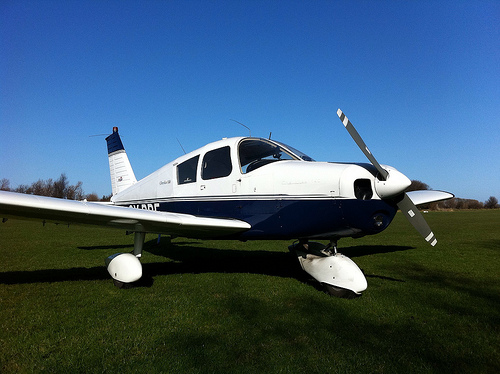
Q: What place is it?
A: It is a field.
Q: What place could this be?
A: It is a field.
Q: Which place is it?
A: It is a field.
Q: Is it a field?
A: Yes, it is a field.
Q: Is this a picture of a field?
A: Yes, it is showing a field.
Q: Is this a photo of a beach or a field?
A: It is showing a field.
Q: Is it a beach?
A: No, it is a field.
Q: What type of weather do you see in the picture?
A: It is clear.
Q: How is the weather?
A: It is clear.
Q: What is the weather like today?
A: It is clear.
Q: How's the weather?
A: It is clear.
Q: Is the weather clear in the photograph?
A: Yes, it is clear.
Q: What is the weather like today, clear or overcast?
A: It is clear.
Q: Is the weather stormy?
A: No, it is clear.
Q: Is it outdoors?
A: Yes, it is outdoors.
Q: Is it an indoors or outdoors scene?
A: It is outdoors.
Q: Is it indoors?
A: No, it is outdoors.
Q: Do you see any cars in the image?
A: No, there are no cars.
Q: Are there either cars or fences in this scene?
A: No, there are no cars or fences.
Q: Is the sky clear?
A: Yes, the sky is clear.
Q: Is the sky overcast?
A: No, the sky is clear.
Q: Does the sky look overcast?
A: No, the sky is clear.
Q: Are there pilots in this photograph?
A: No, there are no pilots.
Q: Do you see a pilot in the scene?
A: No, there are no pilots.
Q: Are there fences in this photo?
A: No, there are no fences.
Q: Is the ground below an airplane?
A: Yes, the ground is below an airplane.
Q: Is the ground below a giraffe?
A: No, the ground is below an airplane.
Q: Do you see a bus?
A: No, there are no buses.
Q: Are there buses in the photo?
A: No, there are no buses.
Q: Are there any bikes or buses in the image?
A: No, there are no buses or bikes.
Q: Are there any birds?
A: No, there are no birds.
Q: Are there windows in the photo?
A: Yes, there is a window.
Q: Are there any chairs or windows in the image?
A: Yes, there is a window.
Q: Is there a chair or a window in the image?
A: Yes, there is a window.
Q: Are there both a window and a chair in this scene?
A: No, there is a window but no chairs.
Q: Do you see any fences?
A: No, there are no fences.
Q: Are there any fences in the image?
A: No, there are no fences.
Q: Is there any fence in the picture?
A: No, there are no fences.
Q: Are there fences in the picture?
A: No, there are no fences.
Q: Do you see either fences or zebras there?
A: No, there are no fences or zebras.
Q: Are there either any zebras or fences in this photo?
A: No, there are no fences or zebras.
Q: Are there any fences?
A: No, there are no fences.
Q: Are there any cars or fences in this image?
A: No, there are no fences or cars.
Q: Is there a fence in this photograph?
A: No, there are no fences.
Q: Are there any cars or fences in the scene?
A: No, there are no fences or cars.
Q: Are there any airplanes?
A: Yes, there is an airplane.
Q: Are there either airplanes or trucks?
A: Yes, there is an airplane.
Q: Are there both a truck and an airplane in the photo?
A: No, there is an airplane but no trucks.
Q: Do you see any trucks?
A: No, there are no trucks.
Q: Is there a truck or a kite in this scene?
A: No, there are no trucks or kites.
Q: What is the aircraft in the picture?
A: The aircraft is an airplane.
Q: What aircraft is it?
A: The aircraft is an airplane.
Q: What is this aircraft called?
A: This is an airplane.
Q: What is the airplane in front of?
A: The airplane is in front of the trees.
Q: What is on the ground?
A: The airplane is on the ground.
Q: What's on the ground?
A: The airplane is on the ground.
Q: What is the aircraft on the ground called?
A: The aircraft is an airplane.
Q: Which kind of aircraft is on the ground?
A: The aircraft is an airplane.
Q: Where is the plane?
A: The plane is on the ground.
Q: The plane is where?
A: The plane is on the ground.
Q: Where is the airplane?
A: The plane is on the ground.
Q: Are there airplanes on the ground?
A: Yes, there is an airplane on the ground.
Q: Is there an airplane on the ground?
A: Yes, there is an airplane on the ground.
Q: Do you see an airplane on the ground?
A: Yes, there is an airplane on the ground.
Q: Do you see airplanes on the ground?
A: Yes, there is an airplane on the ground.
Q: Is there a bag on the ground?
A: No, there is an airplane on the ground.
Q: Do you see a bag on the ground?
A: No, there is an airplane on the ground.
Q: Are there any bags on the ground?
A: No, there is an airplane on the ground.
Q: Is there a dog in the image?
A: No, there are no dogs.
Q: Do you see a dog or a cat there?
A: No, there are no dogs or cats.